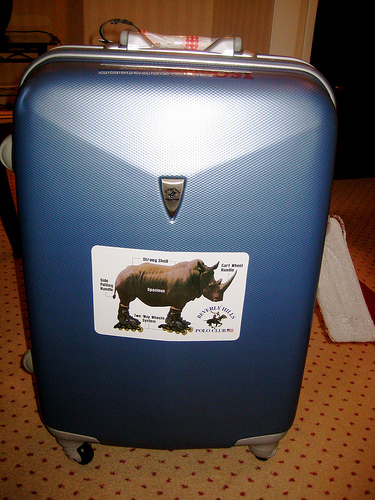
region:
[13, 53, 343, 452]
blue suitcase with a sticker on it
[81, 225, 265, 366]
sticker on the suitcase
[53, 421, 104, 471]
wheel on the suitcase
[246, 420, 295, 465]
wheel on the suitcase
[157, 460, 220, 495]
dots on the carpet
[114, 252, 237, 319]
rhino on the sticker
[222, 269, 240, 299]
horn on the rhino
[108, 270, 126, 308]
tail on the rhino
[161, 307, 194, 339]
rollerblades on the rhino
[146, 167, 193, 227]
logo on the suitcase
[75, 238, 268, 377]
Sticker on the luggage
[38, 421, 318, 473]
Tires on the floor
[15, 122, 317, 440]
Blue suitcase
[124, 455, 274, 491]
Floor is red and tan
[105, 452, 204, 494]
The spots are red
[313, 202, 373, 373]
Cloth on the side of the box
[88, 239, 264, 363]
There is an animal on the sticker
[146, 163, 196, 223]
A triangle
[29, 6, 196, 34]
The wall is made of wood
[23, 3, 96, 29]
The wood is brown and light brown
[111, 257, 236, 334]
A rhino on a sticker.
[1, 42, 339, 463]
Large blue and grey suitcase.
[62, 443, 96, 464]
Grey and black wheel on the bottom left of the suitcase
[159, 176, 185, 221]
Silver triangle symbol thing on the front of a blue suitcase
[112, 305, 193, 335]
Rollerblades on a rhino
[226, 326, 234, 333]
American flag on a white rhino label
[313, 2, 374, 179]
A black door on a room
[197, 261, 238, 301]
The head of a rhino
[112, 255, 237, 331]
A rhino with skates on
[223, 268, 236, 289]
A large horn of a rhino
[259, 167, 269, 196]
blue piece of luggage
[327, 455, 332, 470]
carpet is tan with red dots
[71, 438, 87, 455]
black wheels on luggage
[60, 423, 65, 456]
gray casing on back wheel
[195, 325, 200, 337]
sticker of rhino on luggage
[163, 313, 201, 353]
rhino wearing roller skates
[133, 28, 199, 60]
gray retractable handle on luggage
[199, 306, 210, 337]
sticker says beverly hills polo club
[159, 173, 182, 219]
stainless triangle emblem on bag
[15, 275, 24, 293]
shadow behind blue luggage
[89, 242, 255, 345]
a sticker on a suitcase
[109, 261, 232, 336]
a rhinoceros on roller blades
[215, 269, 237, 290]
the horns of a rhinoceros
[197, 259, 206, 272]
the ear of a rhinoceros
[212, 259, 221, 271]
the ear of a rhinoceros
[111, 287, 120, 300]
the tail of a rhinoceros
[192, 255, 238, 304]
the head of a rhinoceros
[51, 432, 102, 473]
the wheels on a suitcase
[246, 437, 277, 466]
the wheels on a suitcase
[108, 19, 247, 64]
the handle of a suitcase